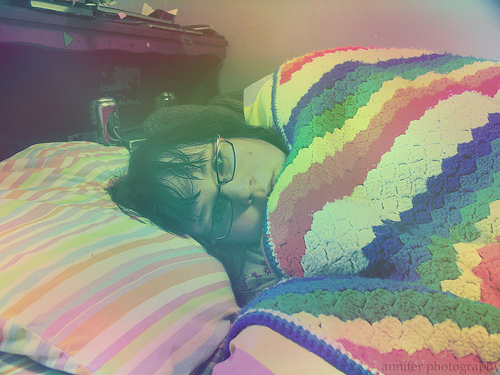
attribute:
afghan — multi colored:
[223, 42, 498, 374]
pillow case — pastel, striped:
[1, 135, 246, 373]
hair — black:
[102, 110, 290, 237]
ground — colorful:
[409, 110, 454, 146]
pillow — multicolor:
[0, 136, 199, 373]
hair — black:
[130, 118, 199, 233]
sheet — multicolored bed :
[238, 57, 498, 352]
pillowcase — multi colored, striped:
[0, 139, 137, 374]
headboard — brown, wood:
[0, 12, 225, 161]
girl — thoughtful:
[103, 115, 290, 305]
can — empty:
[87, 93, 128, 153]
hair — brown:
[103, 98, 287, 270]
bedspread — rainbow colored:
[259, 45, 498, 372]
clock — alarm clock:
[119, 128, 164, 157]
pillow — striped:
[1, 140, 242, 371]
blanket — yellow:
[219, 39, 498, 373]